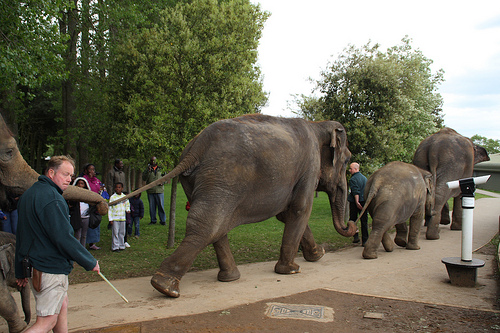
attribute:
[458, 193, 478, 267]
pole — white